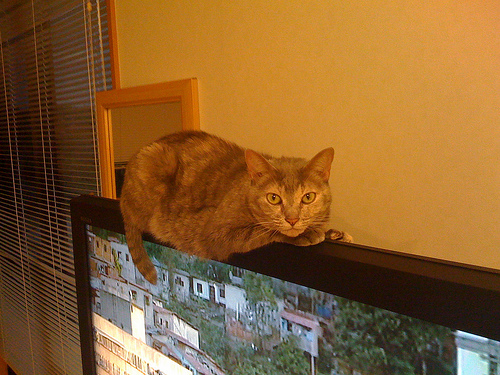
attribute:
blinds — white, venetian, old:
[1, 4, 115, 374]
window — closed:
[1, 2, 112, 373]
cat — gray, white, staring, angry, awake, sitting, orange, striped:
[120, 129, 352, 291]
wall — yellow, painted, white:
[115, 1, 499, 265]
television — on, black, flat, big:
[53, 194, 498, 373]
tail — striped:
[121, 215, 161, 283]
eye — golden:
[264, 188, 318, 205]